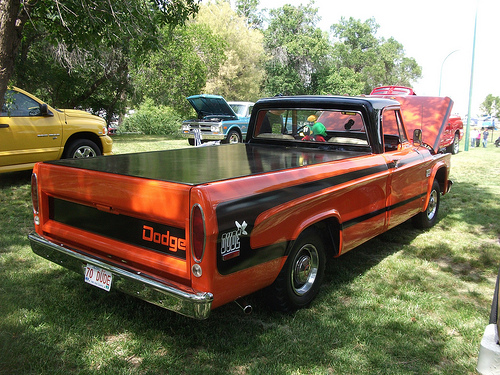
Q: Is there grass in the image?
A: Yes, there is grass.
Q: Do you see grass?
A: Yes, there is grass.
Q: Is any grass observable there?
A: Yes, there is grass.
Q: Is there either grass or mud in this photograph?
A: Yes, there is grass.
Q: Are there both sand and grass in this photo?
A: No, there is grass but no sand.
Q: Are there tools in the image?
A: No, there are no tools.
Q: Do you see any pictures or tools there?
A: No, there are no tools or pictures.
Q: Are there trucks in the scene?
A: Yes, there is a truck.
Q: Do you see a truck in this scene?
A: Yes, there is a truck.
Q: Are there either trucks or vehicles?
A: Yes, there is a truck.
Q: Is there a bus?
A: No, there are no buses.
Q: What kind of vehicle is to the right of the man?
A: The vehicle is a truck.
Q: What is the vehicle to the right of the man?
A: The vehicle is a truck.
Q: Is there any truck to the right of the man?
A: Yes, there is a truck to the right of the man.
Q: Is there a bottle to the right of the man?
A: No, there is a truck to the right of the man.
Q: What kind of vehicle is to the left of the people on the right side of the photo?
A: The vehicle is a truck.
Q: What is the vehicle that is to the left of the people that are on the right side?
A: The vehicle is a truck.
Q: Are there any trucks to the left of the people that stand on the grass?
A: Yes, there is a truck to the left of the people.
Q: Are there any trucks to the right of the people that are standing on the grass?
A: No, the truck is to the left of the people.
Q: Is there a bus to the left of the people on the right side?
A: No, there is a truck to the left of the people.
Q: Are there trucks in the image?
A: Yes, there is a truck.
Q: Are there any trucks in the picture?
A: Yes, there is a truck.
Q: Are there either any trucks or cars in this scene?
A: Yes, there is a truck.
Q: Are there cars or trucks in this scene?
A: Yes, there is a truck.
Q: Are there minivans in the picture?
A: No, there are no minivans.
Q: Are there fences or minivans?
A: No, there are no minivans or fences.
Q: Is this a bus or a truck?
A: This is a truck.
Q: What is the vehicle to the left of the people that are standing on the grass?
A: The vehicle is a truck.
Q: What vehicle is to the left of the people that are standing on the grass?
A: The vehicle is a truck.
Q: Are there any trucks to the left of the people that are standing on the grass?
A: Yes, there is a truck to the left of the people.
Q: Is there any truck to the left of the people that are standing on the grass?
A: Yes, there is a truck to the left of the people.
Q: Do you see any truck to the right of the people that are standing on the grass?
A: No, the truck is to the left of the people.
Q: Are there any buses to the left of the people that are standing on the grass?
A: No, there is a truck to the left of the people.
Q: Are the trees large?
A: Yes, the trees are large.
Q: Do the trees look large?
A: Yes, the trees are large.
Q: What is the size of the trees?
A: The trees are large.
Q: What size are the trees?
A: The trees are large.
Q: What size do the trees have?
A: The trees have large size.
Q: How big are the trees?
A: The trees are large.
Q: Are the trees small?
A: No, the trees are large.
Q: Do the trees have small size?
A: No, the trees are large.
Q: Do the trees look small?
A: No, the trees are large.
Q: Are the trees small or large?
A: The trees are large.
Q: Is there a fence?
A: No, there are no fences.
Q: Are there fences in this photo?
A: No, there are no fences.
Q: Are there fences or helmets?
A: No, there are no fences or helmets.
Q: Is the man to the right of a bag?
A: No, the man is to the right of a truck.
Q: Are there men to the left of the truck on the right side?
A: Yes, there is a man to the left of the truck.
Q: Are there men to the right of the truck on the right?
A: No, the man is to the left of the truck.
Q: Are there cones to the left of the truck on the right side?
A: No, there is a man to the left of the truck.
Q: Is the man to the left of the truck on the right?
A: Yes, the man is to the left of the truck.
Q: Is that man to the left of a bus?
A: No, the man is to the left of the truck.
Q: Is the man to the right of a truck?
A: No, the man is to the left of a truck.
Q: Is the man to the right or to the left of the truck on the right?
A: The man is to the left of the truck.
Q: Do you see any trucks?
A: Yes, there is a truck.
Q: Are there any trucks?
A: Yes, there is a truck.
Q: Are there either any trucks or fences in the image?
A: Yes, there is a truck.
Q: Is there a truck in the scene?
A: Yes, there is a truck.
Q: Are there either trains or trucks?
A: Yes, there is a truck.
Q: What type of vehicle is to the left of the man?
A: The vehicle is a truck.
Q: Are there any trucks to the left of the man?
A: Yes, there is a truck to the left of the man.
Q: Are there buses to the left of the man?
A: No, there is a truck to the left of the man.